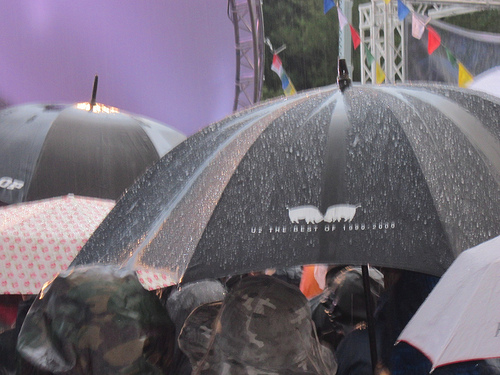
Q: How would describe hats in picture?
A: Military Hats.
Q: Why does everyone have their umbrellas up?
A: It's Raining.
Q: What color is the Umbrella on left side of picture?
A: Pink on White.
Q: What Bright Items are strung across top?
A: Flags.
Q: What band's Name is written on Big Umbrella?
A: U2.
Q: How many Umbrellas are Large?
A: 2.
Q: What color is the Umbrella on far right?
A: White.